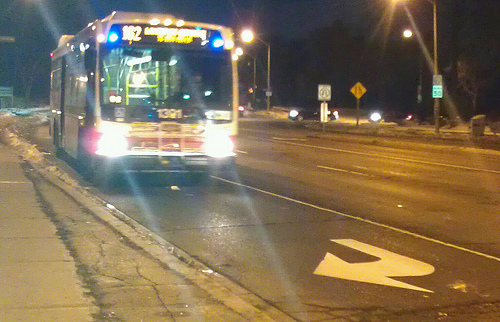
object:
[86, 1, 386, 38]
sky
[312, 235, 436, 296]
arrow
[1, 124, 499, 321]
ground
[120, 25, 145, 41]
number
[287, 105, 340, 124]
car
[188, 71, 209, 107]
driver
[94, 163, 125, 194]
wheel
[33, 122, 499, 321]
street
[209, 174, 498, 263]
line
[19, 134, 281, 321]
cracks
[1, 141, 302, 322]
sidewalk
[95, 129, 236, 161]
headlights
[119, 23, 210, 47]
screen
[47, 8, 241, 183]
bus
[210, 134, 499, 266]
lines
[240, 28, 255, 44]
light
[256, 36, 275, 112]
pole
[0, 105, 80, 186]
snow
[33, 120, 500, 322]
road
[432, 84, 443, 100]
sign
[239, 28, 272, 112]
street light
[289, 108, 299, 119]
headlight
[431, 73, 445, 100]
signs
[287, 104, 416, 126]
cars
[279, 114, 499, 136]
freeway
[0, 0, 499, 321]
scene